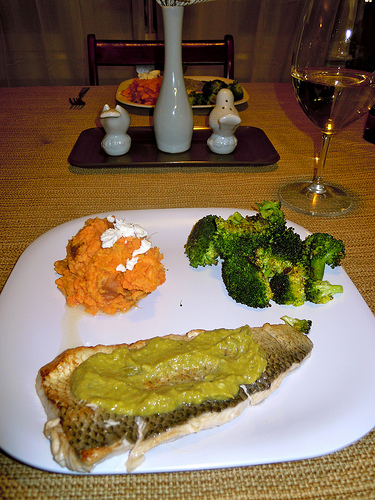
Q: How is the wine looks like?
A: Tasty.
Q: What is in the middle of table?
A: Tray.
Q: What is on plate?
A: Fish.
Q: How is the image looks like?
A: Yummy.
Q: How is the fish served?
A: Mustard sauce.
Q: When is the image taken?
A: Food is on plate.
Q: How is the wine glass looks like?
A: Half-full.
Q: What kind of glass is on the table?
A: Wine glass.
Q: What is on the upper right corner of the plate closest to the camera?
A: Broccoli.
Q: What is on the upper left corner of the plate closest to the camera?
A: Sweet potatoes.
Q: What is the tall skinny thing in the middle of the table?
A: Vase.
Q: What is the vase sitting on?
A: Black tray.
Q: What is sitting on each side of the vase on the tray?
A: Salt and pepper shakers.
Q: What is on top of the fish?
A: Green sauce.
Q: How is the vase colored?
A: White.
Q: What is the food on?
A: Plate.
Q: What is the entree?
A: Fish.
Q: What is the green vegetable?
A: Broccoli.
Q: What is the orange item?
A: Sweet potato.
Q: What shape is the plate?
A: Square.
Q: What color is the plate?
A: White.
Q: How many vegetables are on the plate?
A: Two.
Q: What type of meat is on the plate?
A: Fish.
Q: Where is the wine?
A: In the glass.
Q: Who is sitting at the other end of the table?
A: No one.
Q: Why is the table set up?
A: Getting ready for dinner.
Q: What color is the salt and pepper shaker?
A: White.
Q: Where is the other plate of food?
A: On the other side.